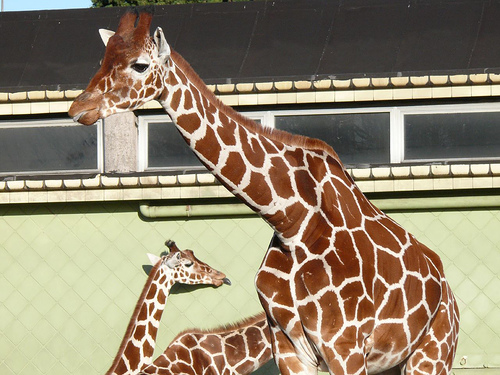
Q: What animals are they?
A: Giraffes.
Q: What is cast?
A: Shadow.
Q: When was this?
A: Daytime.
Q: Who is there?
A: No one.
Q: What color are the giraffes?
A: Spotted brown.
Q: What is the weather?
A: Sunny.